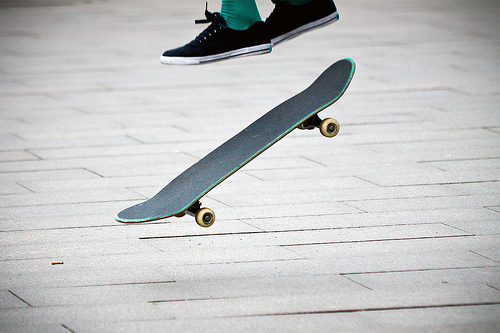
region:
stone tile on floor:
[29, 275, 161, 309]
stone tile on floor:
[191, 269, 292, 327]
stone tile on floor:
[339, 234, 408, 312]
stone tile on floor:
[370, 174, 438, 245]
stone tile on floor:
[257, 178, 327, 230]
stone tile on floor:
[137, 120, 192, 166]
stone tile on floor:
[36, 140, 111, 184]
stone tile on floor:
[46, 86, 115, 132]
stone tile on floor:
[20, 43, 84, 84]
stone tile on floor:
[402, 45, 474, 111]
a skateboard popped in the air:
[115, 52, 365, 229]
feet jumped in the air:
[161, 2, 355, 71]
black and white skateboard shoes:
[156, 18, 276, 67]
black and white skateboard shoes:
[256, 1, 348, 49]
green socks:
[216, 1, 262, 35]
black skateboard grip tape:
[115, 47, 353, 227]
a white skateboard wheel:
[192, 202, 217, 232]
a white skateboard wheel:
[319, 115, 343, 141]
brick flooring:
[5, 2, 495, 329]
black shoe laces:
[196, 6, 224, 30]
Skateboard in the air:
[92, 62, 407, 237]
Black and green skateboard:
[87, 63, 404, 238]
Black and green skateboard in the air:
[82, 54, 410, 244]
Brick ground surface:
[25, 60, 134, 180]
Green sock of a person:
[218, 0, 268, 31]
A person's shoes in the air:
[133, 7, 359, 56]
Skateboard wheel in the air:
[320, 117, 342, 137]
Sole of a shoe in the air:
[161, 41, 270, 61]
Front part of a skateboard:
[112, 160, 245, 245]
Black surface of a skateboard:
[202, 162, 221, 172]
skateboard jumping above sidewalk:
[106, 50, 376, 243]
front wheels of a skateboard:
[185, 197, 215, 235]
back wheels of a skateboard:
[293, 114, 353, 142]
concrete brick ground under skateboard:
[319, 147, 473, 321]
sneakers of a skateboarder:
[158, 5, 360, 70]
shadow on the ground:
[4, 272, 47, 331]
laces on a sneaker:
[191, 4, 223, 27]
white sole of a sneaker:
[155, 41, 272, 70]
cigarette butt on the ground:
[44, 256, 69, 271]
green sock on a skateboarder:
[219, 2, 266, 32]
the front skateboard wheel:
[189, 201, 220, 249]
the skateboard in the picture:
[102, 95, 400, 229]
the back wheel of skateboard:
[312, 103, 336, 139]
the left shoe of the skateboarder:
[171, 25, 273, 69]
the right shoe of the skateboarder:
[266, 2, 351, 38]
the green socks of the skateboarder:
[219, 3, 259, 32]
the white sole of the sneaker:
[157, 51, 294, 71]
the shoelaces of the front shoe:
[196, 8, 221, 25]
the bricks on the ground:
[6, 9, 499, 308]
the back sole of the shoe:
[271, 19, 366, 54]